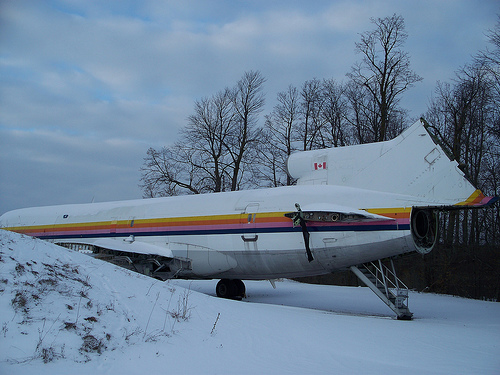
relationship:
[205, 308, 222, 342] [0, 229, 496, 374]
stick on snow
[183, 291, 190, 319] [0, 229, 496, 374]
stick on snow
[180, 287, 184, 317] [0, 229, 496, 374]
stick on snow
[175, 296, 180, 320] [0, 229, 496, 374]
stick on snow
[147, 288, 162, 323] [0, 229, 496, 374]
stick on snow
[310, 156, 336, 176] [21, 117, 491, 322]
canadian flag on plane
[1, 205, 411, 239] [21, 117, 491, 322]
stripes on plane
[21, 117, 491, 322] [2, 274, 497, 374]
plane on snow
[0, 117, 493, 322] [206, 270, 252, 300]
plane has wheel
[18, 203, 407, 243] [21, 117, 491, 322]
stripes on plane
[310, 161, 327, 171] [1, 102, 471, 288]
canadian flag on plane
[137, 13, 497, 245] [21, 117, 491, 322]
trees behind plane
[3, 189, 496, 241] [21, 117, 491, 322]
stripes on plane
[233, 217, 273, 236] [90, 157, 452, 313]
stripe on plane